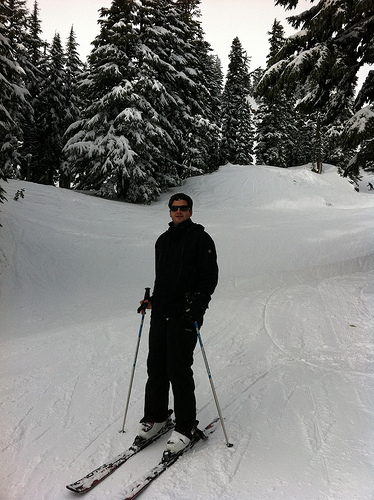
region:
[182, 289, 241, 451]
a blue and white ski pole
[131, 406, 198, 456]
pair of white ski boots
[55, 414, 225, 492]
a pair of black skis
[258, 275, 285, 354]
a groove in the snow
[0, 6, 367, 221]
some snow covered trees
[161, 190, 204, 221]
a man wearing sunglasses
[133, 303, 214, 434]
a pair of black ski pants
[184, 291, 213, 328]
a black snow glove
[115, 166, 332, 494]
a man skiing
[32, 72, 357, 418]
ski path through the trees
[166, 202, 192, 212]
man wearing black sunglasses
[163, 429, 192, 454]
mans boots covered in snow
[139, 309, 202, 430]
man wearing black pants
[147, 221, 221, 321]
man wearing black coat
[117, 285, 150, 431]
man holding silver ski pole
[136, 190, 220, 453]
man skiing down snowy slope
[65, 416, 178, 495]
man wearing black ski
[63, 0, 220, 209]
tall evergreen covered in snow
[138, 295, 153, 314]
man holding pole with bare hand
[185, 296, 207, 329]
man wearing black glove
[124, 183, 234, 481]
Man dressed in black snow gear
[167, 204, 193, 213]
Black sunglasses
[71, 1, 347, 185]
Tall green trees covered with snow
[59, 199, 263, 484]
Man going skiing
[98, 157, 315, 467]
Man standing on skis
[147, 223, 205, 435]
Black snow pants and coat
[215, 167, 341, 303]
Snow slopes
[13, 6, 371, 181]
Green trees with snow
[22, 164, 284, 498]
Man on ski slopes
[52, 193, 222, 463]
Man in black ski clothing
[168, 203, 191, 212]
Sunglasses worn by the skier.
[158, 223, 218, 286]
Black jacket worn by the man on the skis.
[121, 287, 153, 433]
Ski pole in the left hand of the skier.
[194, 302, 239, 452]
Ski pole in the right hand of the skier.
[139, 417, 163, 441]
White ski boot on the skier's left foot.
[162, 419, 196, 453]
White ski boot on the skier's right foot.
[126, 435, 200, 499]
Right ski the man is standing on.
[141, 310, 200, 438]
Black pants worn by the man.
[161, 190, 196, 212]
Short black hair of the man standing on the skis.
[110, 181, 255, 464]
This is a man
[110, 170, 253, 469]
The man is skiing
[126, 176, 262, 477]
The man is wearing all black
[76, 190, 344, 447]
Snow covers the ground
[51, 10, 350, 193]
The sky is grey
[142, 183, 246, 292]
The man is wearing sunglasses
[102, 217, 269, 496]
The man is wearing skis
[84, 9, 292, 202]
There are trees in the background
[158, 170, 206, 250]
The man has black hair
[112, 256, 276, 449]
The man is holding Ski sticks